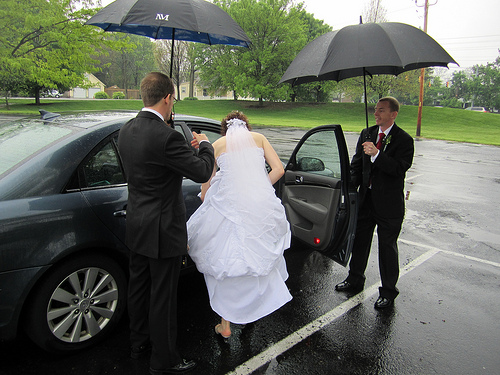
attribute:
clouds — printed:
[143, 25, 230, 46]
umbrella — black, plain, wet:
[274, 14, 459, 141]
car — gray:
[8, 102, 396, 344]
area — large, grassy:
[12, 83, 498, 156]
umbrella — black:
[281, 9, 460, 94]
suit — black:
[349, 122, 433, 309]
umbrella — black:
[82, 0, 247, 81]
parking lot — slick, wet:
[425, 145, 492, 361]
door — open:
[281, 124, 356, 266]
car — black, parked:
[2, 105, 380, 359]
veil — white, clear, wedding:
[223, 116, 275, 223]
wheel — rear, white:
[25, 251, 131, 366]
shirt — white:
[363, 122, 402, 155]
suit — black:
[85, 120, 240, 282]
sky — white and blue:
[118, 18, 221, 58]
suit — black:
[344, 121, 413, 301]